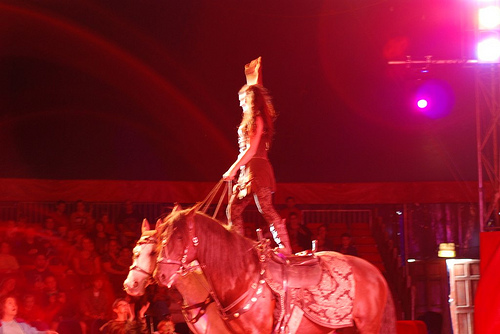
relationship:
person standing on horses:
[223, 84, 292, 258] [114, 200, 402, 328]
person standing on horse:
[223, 84, 292, 258] [153, 205, 393, 328]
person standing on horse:
[223, 84, 292, 258] [121, 216, 340, 329]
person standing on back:
[223, 84, 292, 258] [256, 241, 346, 270]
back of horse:
[256, 241, 346, 270] [153, 205, 393, 328]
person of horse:
[223, 84, 292, 258] [121, 216, 340, 329]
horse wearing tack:
[153, 205, 393, 328] [163, 233, 356, 331]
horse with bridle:
[120, 215, 224, 332] [127, 232, 157, 282]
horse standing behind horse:
[120, 215, 224, 332] [153, 205, 393, 328]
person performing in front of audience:
[223, 84, 292, 258] [3, 196, 352, 328]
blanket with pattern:
[301, 250, 355, 328] [300, 249, 356, 329]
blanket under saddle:
[301, 250, 355, 328] [256, 227, 324, 288]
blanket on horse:
[301, 250, 355, 328] [153, 205, 393, 328]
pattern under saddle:
[300, 249, 356, 329] [256, 227, 324, 288]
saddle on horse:
[256, 227, 324, 288] [153, 205, 393, 328]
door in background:
[447, 254, 480, 331] [389, 209, 495, 322]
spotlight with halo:
[408, 79, 456, 119] [408, 81, 455, 121]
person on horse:
[223, 84, 292, 258] [153, 205, 393, 328]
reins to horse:
[185, 169, 234, 229] [123, 218, 233, 334]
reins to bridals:
[185, 169, 234, 229] [130, 225, 196, 287]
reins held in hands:
[185, 169, 234, 229] [219, 173, 235, 186]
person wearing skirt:
[223, 84, 292, 258] [230, 150, 274, 200]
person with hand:
[223, 84, 292, 258] [250, 55, 264, 88]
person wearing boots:
[223, 84, 292, 258] [227, 216, 288, 256]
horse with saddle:
[153, 205, 393, 328] [256, 227, 324, 288]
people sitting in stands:
[3, 196, 352, 332] [3, 177, 418, 329]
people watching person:
[3, 196, 352, 332] [223, 84, 292, 258]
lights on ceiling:
[406, 3, 498, 114] [3, 6, 488, 181]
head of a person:
[236, 84, 266, 113] [221, 55, 293, 259]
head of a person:
[88, 276, 102, 287] [80, 274, 110, 319]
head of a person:
[112, 298, 129, 319] [103, 296, 137, 332]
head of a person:
[0, 293, 16, 317] [3, 294, 38, 331]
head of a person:
[37, 270, 65, 310] [39, 274, 63, 306]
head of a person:
[82, 195, 143, 235] [77, 195, 128, 265]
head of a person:
[89, 216, 111, 241] [84, 213, 110, 254]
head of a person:
[118, 196, 141, 217] [111, 190, 146, 235]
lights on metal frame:
[475, 0, 500, 66] [471, 7, 484, 221]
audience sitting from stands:
[0, 197, 359, 334] [8, 177, 458, 332]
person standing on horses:
[223, 84, 292, 258] [118, 190, 409, 324]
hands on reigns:
[216, 170, 239, 183] [185, 176, 235, 231]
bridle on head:
[157, 216, 195, 281] [141, 200, 210, 293]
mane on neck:
[193, 207, 256, 275] [188, 210, 246, 303]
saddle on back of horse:
[248, 226, 342, 300] [145, 199, 395, 332]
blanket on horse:
[265, 251, 355, 329] [153, 205, 393, 328]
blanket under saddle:
[265, 251, 355, 329] [252, 234, 327, 303]